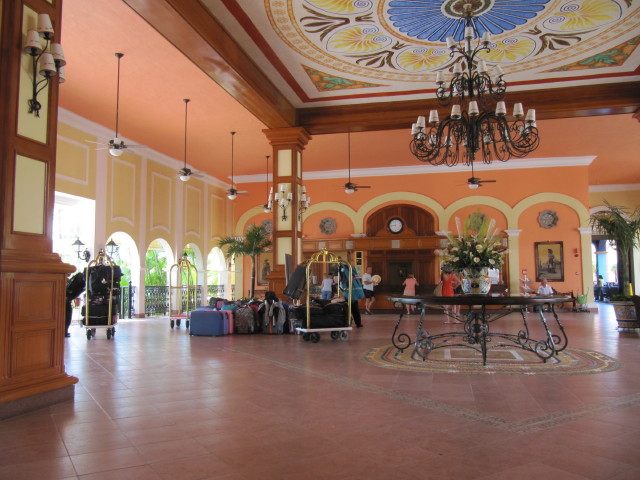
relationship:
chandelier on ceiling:
[397, 0, 548, 174] [240, 2, 636, 74]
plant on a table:
[433, 220, 512, 293] [363, 263, 572, 399]